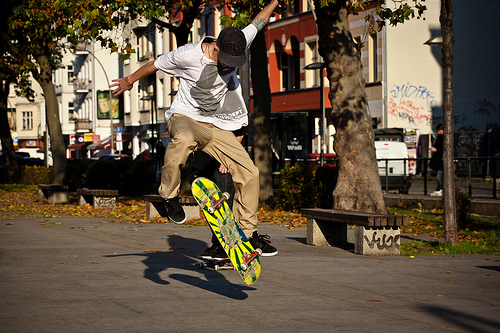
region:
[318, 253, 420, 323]
part of the ground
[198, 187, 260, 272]
base of the skateboard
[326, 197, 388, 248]
part of a bench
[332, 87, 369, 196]
stem of a tree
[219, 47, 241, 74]
part of a cap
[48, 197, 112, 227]
part of dry leaves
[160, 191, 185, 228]
a shoe on the right leg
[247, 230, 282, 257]
shore on the left leg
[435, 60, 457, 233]
stem of another tree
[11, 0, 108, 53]
some part of tree branches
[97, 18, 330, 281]
man jumping over his board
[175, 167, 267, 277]
yellow board with black lines radiating from center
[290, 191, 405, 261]
bench with graffitit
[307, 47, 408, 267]
tall tree growing behind bench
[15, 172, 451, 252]
fallen leaves on park grounds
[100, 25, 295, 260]
skateboarder wearing white shirt and tan pants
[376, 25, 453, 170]
graffiti sprayed on side of building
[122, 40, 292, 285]
second skateboarder behind jumping one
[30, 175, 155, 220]
orange, green and yellow leaves clustered around bench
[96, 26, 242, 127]
arm extended behind skateboarder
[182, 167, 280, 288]
Green and yellow skateboard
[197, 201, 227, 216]
White wheel on a skateboard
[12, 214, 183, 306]
Gray paved area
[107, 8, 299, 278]
Boy riding a skateboard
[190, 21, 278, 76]
Black hat on a boy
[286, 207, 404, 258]
Gray and brown bench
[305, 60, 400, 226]
Brown tree by a bench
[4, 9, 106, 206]
Green and brown tree in a park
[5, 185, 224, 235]
Brown and yellow leaves on the ground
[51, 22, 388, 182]
Red and white buildings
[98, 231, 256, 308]
Man's shadow on the ground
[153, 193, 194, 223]
Man's left black sneaker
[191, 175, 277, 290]
Skateboard man is performing on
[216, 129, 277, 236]
Man's left leg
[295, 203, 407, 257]
Bench to the man's right closest to us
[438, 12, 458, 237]
Very narrow tree trunk with no branches to the man's right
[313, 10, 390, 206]
Thickest tree trunk above the first bench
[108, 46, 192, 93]
Man's outstretched right arm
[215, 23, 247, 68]
Black cap on the man's head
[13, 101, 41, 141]
Window in the last building we can see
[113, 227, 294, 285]
man's shadow on brown cement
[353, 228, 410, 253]
graffiti on side of bench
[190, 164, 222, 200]
green lines on yellow skate board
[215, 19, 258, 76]
black cap with wide brim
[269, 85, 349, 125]
orange ledge on building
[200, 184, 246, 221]
silver wheels on skate board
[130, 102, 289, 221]
tan cargo pants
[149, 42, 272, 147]
white short sleeve shirt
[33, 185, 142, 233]
gold and orange leaves on the ground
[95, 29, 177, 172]
large white apartment building